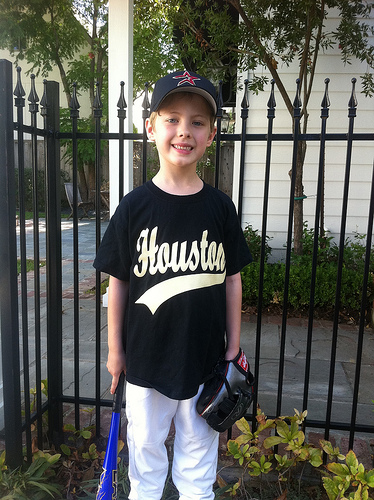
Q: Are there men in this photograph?
A: No, there are no men.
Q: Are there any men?
A: No, there are no men.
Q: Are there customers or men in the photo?
A: No, there are no men or customers.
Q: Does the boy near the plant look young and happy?
A: Yes, the boy is young and happy.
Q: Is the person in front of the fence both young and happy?
A: Yes, the boy is young and happy.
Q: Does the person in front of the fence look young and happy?
A: Yes, the boy is young and happy.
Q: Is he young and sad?
A: No, the boy is young but happy.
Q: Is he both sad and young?
A: No, the boy is young but happy.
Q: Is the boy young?
A: Yes, the boy is young.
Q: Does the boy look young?
A: Yes, the boy is young.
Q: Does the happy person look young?
A: Yes, the boy is young.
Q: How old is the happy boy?
A: The boy is young.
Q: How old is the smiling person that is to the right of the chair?
A: The boy is young.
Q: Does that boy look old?
A: No, the boy is young.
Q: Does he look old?
A: No, the boy is young.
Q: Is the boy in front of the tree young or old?
A: The boy is young.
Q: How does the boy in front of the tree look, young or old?
A: The boy is young.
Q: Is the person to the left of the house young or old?
A: The boy is young.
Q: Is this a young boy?
A: Yes, this is a young boy.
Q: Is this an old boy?
A: No, this is a young boy.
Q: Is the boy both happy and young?
A: Yes, the boy is happy and young.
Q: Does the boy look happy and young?
A: Yes, the boy is happy and young.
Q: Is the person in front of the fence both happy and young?
A: Yes, the boy is happy and young.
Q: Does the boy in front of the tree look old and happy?
A: No, the boy is happy but young.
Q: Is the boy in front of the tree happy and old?
A: No, the boy is happy but young.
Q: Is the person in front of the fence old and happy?
A: No, the boy is happy but young.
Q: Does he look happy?
A: Yes, the boy is happy.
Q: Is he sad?
A: No, the boy is happy.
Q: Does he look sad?
A: No, the boy is happy.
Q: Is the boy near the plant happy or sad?
A: The boy is happy.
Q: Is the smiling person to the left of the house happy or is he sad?
A: The boy is happy.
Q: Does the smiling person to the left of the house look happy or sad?
A: The boy is happy.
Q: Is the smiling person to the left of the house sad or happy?
A: The boy is happy.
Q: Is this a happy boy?
A: Yes, this is a happy boy.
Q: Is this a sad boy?
A: No, this is a happy boy.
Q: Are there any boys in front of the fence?
A: Yes, there is a boy in front of the fence.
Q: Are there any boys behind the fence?
A: No, the boy is in front of the fence.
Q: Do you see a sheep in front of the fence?
A: No, there is a boy in front of the fence.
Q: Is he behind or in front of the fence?
A: The boy is in front of the fence.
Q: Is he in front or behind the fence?
A: The boy is in front of the fence.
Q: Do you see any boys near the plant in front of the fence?
A: Yes, there is a boy near the plant.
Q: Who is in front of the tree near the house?
A: The boy is in front of the tree.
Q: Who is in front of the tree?
A: The boy is in front of the tree.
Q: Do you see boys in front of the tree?
A: Yes, there is a boy in front of the tree.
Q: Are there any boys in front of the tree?
A: Yes, there is a boy in front of the tree.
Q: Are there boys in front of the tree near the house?
A: Yes, there is a boy in front of the tree.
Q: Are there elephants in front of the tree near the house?
A: No, there is a boy in front of the tree.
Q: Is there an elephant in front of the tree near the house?
A: No, there is a boy in front of the tree.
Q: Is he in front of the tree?
A: Yes, the boy is in front of the tree.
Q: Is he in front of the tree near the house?
A: Yes, the boy is in front of the tree.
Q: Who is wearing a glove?
A: The boy is wearing a glove.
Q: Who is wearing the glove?
A: The boy is wearing a glove.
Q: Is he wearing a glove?
A: Yes, the boy is wearing a glove.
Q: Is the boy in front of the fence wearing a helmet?
A: No, the boy is wearing a glove.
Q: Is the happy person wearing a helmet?
A: No, the boy is wearing a glove.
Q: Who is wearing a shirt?
A: The boy is wearing a shirt.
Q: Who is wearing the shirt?
A: The boy is wearing a shirt.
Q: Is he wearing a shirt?
A: Yes, the boy is wearing a shirt.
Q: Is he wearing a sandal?
A: No, the boy is wearing a shirt.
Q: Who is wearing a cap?
A: The boy is wearing a cap.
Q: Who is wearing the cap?
A: The boy is wearing a cap.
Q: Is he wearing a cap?
A: Yes, the boy is wearing a cap.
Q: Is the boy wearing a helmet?
A: No, the boy is wearing a cap.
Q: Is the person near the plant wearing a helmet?
A: No, the boy is wearing a cap.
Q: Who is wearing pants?
A: The boy is wearing pants.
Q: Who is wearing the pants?
A: The boy is wearing pants.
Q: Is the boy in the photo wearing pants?
A: Yes, the boy is wearing pants.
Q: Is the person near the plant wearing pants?
A: Yes, the boy is wearing pants.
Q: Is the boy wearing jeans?
A: No, the boy is wearing pants.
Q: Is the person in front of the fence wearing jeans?
A: No, the boy is wearing pants.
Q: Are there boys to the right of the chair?
A: Yes, there is a boy to the right of the chair.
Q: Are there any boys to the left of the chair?
A: No, the boy is to the right of the chair.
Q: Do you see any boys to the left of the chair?
A: No, the boy is to the right of the chair.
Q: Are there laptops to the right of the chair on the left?
A: No, there is a boy to the right of the chair.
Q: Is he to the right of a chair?
A: Yes, the boy is to the right of a chair.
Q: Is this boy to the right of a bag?
A: No, the boy is to the right of a chair.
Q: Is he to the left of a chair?
A: No, the boy is to the right of a chair.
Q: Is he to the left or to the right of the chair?
A: The boy is to the right of the chair.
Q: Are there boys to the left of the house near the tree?
A: Yes, there is a boy to the left of the house.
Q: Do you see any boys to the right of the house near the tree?
A: No, the boy is to the left of the house.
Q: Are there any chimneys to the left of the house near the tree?
A: No, there is a boy to the left of the house.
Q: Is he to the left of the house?
A: Yes, the boy is to the left of the house.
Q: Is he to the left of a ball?
A: No, the boy is to the left of the house.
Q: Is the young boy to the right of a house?
A: No, the boy is to the left of a house.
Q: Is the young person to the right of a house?
A: No, the boy is to the left of a house.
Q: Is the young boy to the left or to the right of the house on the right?
A: The boy is to the left of the house.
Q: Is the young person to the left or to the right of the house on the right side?
A: The boy is to the left of the house.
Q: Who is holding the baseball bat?
A: The boy is holding the baseball bat.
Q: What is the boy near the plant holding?
A: The boy is holding the baseball bat.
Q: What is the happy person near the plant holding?
A: The boy is holding the baseball bat.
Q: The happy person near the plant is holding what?
A: The boy is holding the baseball bat.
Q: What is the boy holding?
A: The boy is holding the baseball bat.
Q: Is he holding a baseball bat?
A: Yes, the boy is holding a baseball bat.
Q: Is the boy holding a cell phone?
A: No, the boy is holding a baseball bat.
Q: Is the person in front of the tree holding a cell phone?
A: No, the boy is holding a baseball bat.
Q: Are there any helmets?
A: No, there are no helmets.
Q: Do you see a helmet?
A: No, there are no helmets.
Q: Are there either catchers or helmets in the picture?
A: No, there are no helmets or catchers.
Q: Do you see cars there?
A: No, there are no cars.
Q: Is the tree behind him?
A: Yes, the tree is behind a boy.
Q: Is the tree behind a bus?
A: No, the tree is behind a boy.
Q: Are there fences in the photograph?
A: Yes, there is a fence.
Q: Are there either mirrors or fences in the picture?
A: Yes, there is a fence.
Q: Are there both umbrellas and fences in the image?
A: No, there is a fence but no umbrellas.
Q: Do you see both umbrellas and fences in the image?
A: No, there is a fence but no umbrellas.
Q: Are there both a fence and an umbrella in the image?
A: No, there is a fence but no umbrellas.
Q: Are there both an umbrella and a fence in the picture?
A: No, there is a fence but no umbrellas.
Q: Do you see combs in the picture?
A: No, there are no combs.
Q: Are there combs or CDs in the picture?
A: No, there are no combs or cds.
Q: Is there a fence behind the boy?
A: Yes, there is a fence behind the boy.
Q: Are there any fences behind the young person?
A: Yes, there is a fence behind the boy.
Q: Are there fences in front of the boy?
A: No, the fence is behind the boy.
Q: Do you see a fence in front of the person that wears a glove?
A: No, the fence is behind the boy.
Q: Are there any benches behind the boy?
A: No, there is a fence behind the boy.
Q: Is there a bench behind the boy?
A: No, there is a fence behind the boy.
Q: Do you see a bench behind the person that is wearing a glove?
A: No, there is a fence behind the boy.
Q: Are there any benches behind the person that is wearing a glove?
A: No, there is a fence behind the boy.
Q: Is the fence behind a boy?
A: Yes, the fence is behind a boy.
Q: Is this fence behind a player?
A: No, the fence is behind a boy.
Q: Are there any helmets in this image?
A: No, there are no helmets.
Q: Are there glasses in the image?
A: No, there are no glasses.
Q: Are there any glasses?
A: No, there are no glasses.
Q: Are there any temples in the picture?
A: No, there are no temples.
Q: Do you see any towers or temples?
A: No, there are no temples or towers.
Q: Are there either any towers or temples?
A: No, there are no temples or towers.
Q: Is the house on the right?
A: Yes, the house is on the right of the image.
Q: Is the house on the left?
A: No, the house is on the right of the image.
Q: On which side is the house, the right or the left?
A: The house is on the right of the image.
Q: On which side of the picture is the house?
A: The house is on the right of the image.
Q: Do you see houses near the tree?
A: Yes, there is a house near the tree.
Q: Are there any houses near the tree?
A: Yes, there is a house near the tree.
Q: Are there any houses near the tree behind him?
A: Yes, there is a house near the tree.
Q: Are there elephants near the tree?
A: No, there is a house near the tree.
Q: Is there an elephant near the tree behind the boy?
A: No, there is a house near the tree.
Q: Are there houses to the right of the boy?
A: Yes, there is a house to the right of the boy.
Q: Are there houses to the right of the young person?
A: Yes, there is a house to the right of the boy.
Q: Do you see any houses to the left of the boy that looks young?
A: No, the house is to the right of the boy.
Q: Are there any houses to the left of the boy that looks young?
A: No, the house is to the right of the boy.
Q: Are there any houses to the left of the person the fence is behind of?
A: No, the house is to the right of the boy.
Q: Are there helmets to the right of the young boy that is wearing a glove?
A: No, there is a house to the right of the boy.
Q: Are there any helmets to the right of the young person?
A: No, there is a house to the right of the boy.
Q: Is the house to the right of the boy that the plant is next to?
A: Yes, the house is to the right of the boy.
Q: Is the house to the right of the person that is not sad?
A: Yes, the house is to the right of the boy.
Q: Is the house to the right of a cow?
A: No, the house is to the right of the boy.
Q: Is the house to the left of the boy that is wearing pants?
A: No, the house is to the right of the boy.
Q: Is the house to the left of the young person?
A: No, the house is to the right of the boy.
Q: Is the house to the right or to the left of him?
A: The house is to the right of the boy.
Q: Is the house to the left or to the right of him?
A: The house is to the right of the boy.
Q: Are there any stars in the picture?
A: Yes, there is a star.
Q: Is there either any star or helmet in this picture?
A: Yes, there is a star.